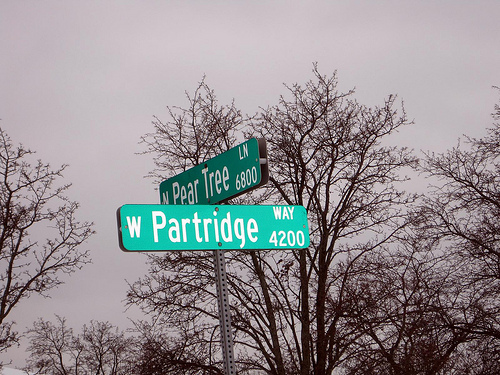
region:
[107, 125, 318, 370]
two signs on top of pole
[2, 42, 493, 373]
trees on back of signs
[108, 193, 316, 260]
white letters of a sign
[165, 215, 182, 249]
the letter is a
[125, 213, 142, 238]
white letter on sign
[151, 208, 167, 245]
white letter on sign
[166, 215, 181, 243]
white letter on sign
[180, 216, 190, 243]
white letter on sign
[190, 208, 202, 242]
white letter on sign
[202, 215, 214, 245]
white letter on sign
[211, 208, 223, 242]
white letter on sign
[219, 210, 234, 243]
white letter on sign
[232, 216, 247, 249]
white letter on sign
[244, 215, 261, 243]
white letter on sign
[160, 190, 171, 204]
white letter on sign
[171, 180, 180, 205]
white letter on sign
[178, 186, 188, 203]
white letter on sign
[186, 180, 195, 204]
white letter on sign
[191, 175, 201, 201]
white letter on sign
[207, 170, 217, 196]
white letter on sign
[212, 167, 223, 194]
white letter on sign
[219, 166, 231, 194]
white letter on sign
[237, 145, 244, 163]
white letter on sign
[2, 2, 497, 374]
hazy gray sky beyond trees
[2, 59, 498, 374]
row of leafless trees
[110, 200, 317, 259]
green rectangular street sign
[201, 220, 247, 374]
gray metal pole with signs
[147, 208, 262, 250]
Partridge in white letters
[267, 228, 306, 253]
4200 on bottom sign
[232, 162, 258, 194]
6800 on top sign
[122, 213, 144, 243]
white letter W on sign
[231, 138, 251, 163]
white letters LN on sign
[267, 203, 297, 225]
WAY in white letters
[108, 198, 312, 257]
green and white rectangular street sign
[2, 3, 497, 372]
cloudy hazy sky beyond trees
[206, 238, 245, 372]
gray metal sign pole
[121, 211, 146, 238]
white letter W on sign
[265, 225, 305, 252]
white 4200 on sign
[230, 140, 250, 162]
white LN on sign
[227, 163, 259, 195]
white 6800 on sign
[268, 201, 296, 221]
WAY in white letters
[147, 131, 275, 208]
the sign shaped rectangle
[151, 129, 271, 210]
the words are color white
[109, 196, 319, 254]
a rectangular sign color green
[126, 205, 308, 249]
the name of the street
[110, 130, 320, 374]
a green and white street sign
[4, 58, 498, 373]
a leafless group of trees in the background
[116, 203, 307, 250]
a green road sign with white writing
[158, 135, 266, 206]
a green road sign with white colored writing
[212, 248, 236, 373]
a silver metal sign pole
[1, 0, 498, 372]
a gray overcast sky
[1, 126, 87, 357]
a bare tree on the left side of the sign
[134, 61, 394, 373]
tall bare trees behind the signs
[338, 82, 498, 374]
bare trees to the right of the signs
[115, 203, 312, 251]
a road sign with the number 4200 on the sign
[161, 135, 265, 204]
a road sign with the number 6800 on the sign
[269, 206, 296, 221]
the word WAY in white on a green background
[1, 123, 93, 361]
a tree in a field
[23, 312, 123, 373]
a cow in a field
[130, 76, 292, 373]
a cow in a field